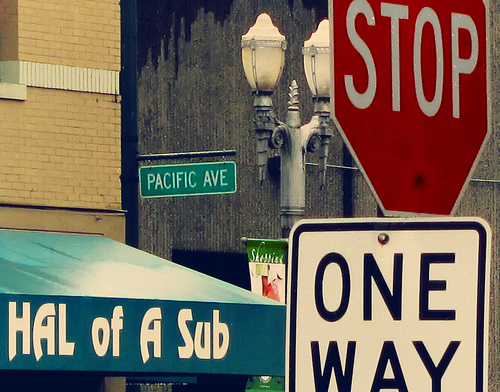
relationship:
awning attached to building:
[1, 232, 258, 326] [2, 0, 287, 377]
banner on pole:
[137, 159, 236, 197] [124, 152, 245, 163]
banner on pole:
[137, 159, 236, 197] [121, 0, 141, 243]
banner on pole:
[137, 159, 236, 197] [132, 149, 237, 159]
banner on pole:
[137, 159, 236, 197] [117, 0, 142, 247]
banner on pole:
[137, 159, 236, 197] [136, 147, 236, 160]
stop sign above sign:
[326, 0, 495, 223] [285, 216, 492, 390]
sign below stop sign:
[285, 216, 492, 390] [326, 0, 495, 223]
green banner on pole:
[223, 216, 314, 392] [232, 11, 354, 246]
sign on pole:
[285, 216, 492, 390] [294, 91, 486, 389]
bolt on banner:
[376, 233, 390, 248] [137, 159, 236, 197]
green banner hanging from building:
[199, 193, 332, 359] [136, 1, 498, 390]